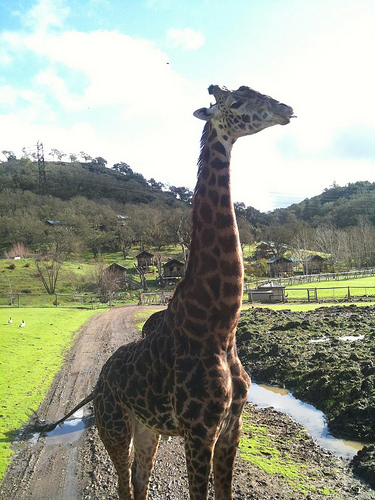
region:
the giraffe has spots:
[73, 235, 253, 469]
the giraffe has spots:
[142, 141, 273, 336]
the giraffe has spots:
[136, 108, 314, 279]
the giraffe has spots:
[109, 44, 232, 313]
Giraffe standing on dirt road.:
[34, 54, 302, 492]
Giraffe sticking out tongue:
[181, 67, 310, 144]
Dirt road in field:
[51, 319, 255, 497]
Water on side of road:
[230, 347, 342, 462]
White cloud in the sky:
[28, 13, 189, 142]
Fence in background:
[249, 276, 345, 317]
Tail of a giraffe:
[7, 373, 120, 455]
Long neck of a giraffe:
[188, 117, 251, 349]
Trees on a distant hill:
[23, 144, 120, 181]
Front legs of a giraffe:
[170, 433, 243, 497]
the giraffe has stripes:
[90, 74, 350, 364]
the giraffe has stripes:
[99, 78, 297, 225]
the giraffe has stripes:
[53, 130, 272, 375]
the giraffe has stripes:
[142, 30, 305, 287]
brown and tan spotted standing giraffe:
[41, 71, 301, 497]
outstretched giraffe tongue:
[282, 109, 299, 121]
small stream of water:
[248, 366, 368, 459]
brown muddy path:
[0, 307, 148, 495]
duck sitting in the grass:
[17, 317, 24, 329]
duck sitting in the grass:
[5, 314, 13, 324]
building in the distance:
[263, 249, 328, 278]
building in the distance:
[132, 246, 152, 274]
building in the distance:
[159, 256, 182, 281]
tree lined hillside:
[2, 141, 373, 250]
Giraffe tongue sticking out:
[286, 114, 301, 122]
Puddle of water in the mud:
[261, 377, 361, 455]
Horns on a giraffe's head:
[206, 82, 236, 100]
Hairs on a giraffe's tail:
[26, 410, 61, 434]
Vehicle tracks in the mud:
[19, 386, 83, 497]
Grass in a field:
[3, 340, 45, 395]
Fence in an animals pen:
[284, 287, 372, 302]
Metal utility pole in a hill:
[33, 140, 51, 193]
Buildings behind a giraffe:
[98, 242, 187, 278]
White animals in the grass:
[5, 309, 32, 333]